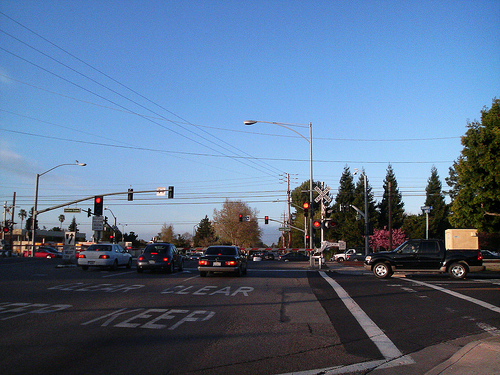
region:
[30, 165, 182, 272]
a traffic signal.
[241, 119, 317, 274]
a street light near a street.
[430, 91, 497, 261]
a tree filled with lots of leaves.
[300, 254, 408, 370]
a cross walk line.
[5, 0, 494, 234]
a clear blue sky.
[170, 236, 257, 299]
a car waiting at a light.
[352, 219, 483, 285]
a truck sitting on a cross walk.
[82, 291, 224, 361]
the word keep on the road.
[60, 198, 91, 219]
a green street sign.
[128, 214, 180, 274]
a tree with lots of leaves.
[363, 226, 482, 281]
black truck hauling large wooden box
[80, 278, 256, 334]
keep clear notice painted on road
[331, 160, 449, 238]
row of four pine trees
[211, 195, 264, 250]
tree with autumn leaves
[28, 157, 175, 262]
combination of lighting and traffic lights on same pole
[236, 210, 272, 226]
suspended traffic lights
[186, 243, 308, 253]
railroad crossing gate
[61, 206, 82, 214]
street sign suspended from pole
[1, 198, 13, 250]
railroad crossing sign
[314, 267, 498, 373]
empty pedestrian crosswalk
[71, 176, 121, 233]
red light over road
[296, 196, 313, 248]
red light on pole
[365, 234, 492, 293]
black pickup truck on road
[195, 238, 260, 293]
red brake lights on car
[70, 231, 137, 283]
white car on road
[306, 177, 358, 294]
railroad crossing signal on pole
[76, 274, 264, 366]
white writing on road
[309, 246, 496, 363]
white lines painted on road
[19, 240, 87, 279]
red car in road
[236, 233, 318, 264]
red and white crossing rail down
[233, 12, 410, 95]
The sky is blue.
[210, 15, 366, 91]
The sky is clear.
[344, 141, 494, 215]
Some trees are growing in the background.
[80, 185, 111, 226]
A traffic light.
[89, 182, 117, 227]
The traffic light is red.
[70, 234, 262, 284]
A row of cars stopped at the light.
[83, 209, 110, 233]
A street sign.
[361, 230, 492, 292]
A black truck is to the right.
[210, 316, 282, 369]
The asphalt is black.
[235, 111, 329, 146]
A street light.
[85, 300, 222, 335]
The word keep painted on the street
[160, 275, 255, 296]
The word clear painted on the street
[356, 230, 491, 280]
Pickup truck negotiating traffic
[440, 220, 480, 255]
Container in back of the pickup truck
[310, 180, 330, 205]
Railroad crossing signs on pole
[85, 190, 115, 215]
Traffic signal at the intersection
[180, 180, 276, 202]
Power wires strung between utility poles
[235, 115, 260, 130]
Light for keeping street lit at night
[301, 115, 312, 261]
Vertical support pole for streetlight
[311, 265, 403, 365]
Crosswalk painted on the street